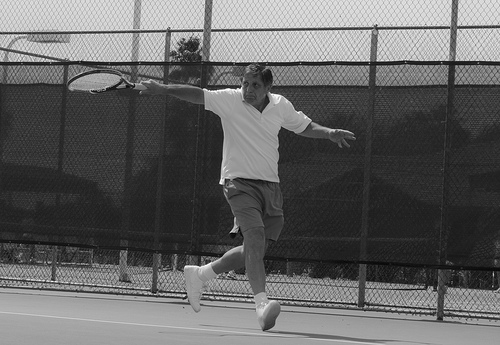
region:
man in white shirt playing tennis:
[77, 62, 372, 332]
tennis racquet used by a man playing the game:
[65, 55, 155, 105]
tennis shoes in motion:
[246, 287, 286, 329]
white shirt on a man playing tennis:
[201, 85, 312, 190]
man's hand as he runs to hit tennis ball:
[325, 120, 360, 150]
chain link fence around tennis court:
[56, 255, 136, 295]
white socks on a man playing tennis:
[200, 263, 220, 284]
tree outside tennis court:
[180, 33, 212, 83]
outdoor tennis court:
[18, 295, 128, 337]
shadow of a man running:
[231, 62, 284, 113]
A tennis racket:
[57, 51, 153, 116]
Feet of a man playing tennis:
[152, 246, 307, 340]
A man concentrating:
[226, 54, 277, 111]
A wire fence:
[320, 12, 423, 60]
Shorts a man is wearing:
[216, 169, 328, 254]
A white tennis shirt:
[186, 85, 312, 192]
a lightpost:
[4, 17, 79, 90]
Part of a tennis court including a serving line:
[45, 305, 115, 342]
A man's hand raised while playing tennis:
[312, 111, 369, 166]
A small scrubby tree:
[143, 30, 213, 90]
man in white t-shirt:
[138, 52, 356, 331]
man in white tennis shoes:
[140, 61, 355, 332]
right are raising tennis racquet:
[66, 66, 225, 120]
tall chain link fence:
[0, 2, 499, 323]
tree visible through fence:
[125, 28, 217, 263]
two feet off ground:
[180, 262, 283, 333]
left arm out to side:
[278, 93, 357, 148]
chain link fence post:
[436, 2, 461, 319]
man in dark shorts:
[139, 64, 357, 330]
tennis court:
[1, 287, 498, 343]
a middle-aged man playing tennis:
[162, 44, 337, 343]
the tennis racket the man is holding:
[49, 58, 160, 105]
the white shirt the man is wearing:
[197, 83, 302, 183]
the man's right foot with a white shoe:
[247, 294, 285, 327]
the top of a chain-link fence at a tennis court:
[329, 15, 497, 83]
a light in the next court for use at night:
[9, 15, 84, 70]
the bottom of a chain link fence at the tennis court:
[304, 262, 495, 331]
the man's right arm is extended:
[287, 96, 396, 161]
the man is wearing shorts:
[215, 170, 289, 247]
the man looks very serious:
[234, 70, 269, 110]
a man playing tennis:
[64, 62, 353, 333]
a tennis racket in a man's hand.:
[65, 67, 154, 93]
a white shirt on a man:
[202, 82, 317, 184]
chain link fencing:
[0, 0, 498, 324]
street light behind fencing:
[2, 26, 71, 280]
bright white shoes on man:
[182, 261, 284, 331]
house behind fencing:
[222, 141, 498, 292]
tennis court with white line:
[0, 287, 498, 343]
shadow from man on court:
[262, 320, 403, 342]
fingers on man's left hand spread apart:
[327, 125, 357, 149]